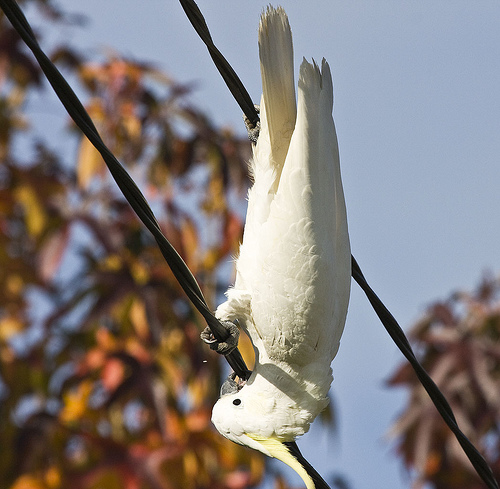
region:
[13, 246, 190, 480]
Multi-colored leaves of the tree/branch on the left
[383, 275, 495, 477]
Leaves to the right of the hanging bird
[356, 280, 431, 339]
Black wire to the right of the bird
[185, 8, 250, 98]
Black wire in the sky near the tip of the bird's tail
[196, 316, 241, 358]
Bird's claw gripping the wire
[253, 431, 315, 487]
Light yellow feather on the top of the bird's head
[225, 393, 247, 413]
Bird's tiny black eye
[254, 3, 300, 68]
Highest reaching tip of the birds tail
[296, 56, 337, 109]
Lower of the two tips of the bird's tail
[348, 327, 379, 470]
Sky between the wires to the right of the bird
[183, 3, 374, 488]
A white bird upside down on a wire, biting it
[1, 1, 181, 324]
Part of a black wire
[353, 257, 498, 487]
Black wire behind the bird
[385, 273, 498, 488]
A blurred image of a tree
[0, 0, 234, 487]
Colorful, but blurry image of a tree in the background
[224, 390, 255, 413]
The bird's black eye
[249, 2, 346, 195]
The bird's white tail feathers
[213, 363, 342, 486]
The bird's head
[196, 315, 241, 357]
The bird's foot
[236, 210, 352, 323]
White feathery body of the bird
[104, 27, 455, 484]
White parrot on wires.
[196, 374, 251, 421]
Black eye on white bird.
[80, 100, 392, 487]
Black wire in parrot's claw.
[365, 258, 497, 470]
Trees behind parrots.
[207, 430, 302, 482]
Yellow feathers on parrots head.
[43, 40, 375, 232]
Blue trees by the leaves.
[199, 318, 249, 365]
Parrot claw on wire.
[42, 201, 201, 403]
Orange and yellow leaves on tree.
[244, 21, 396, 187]
Tail feathers on white bird.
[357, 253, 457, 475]
Black electrical wire.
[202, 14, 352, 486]
Bird on powerline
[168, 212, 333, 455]
Upside bird.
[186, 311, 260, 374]
Birds feet gripped the wires.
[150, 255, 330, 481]
Cockatoo on a line outside.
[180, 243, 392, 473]
Bird with white feathers.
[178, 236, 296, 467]
Bird with feathers outside.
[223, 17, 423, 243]
Bird tail feathers.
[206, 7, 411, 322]
Bird's wings.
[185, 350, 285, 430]
Bird is biting the wire.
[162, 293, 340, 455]
Bird is using it's beak to bite the wire.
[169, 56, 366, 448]
this is a parrot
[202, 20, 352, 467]
the parrot is upside down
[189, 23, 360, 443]
the parrot is white in color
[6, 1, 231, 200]
the parrot is hanging on a wire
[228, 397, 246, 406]
the parrot has black eye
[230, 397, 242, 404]
the parrot has small eye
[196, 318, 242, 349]
the feet are holding the wire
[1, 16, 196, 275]
the wire is folded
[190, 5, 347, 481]
the parrot is clean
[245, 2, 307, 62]
the parrot has long tail